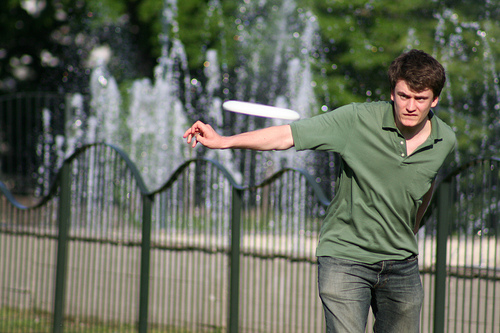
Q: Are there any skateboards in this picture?
A: No, there are no skateboards.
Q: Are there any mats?
A: No, there are no mats.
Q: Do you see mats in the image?
A: No, there are no mats.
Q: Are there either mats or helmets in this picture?
A: No, there are no mats or helmets.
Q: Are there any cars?
A: No, there are no cars.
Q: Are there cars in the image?
A: No, there are no cars.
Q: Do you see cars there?
A: No, there are no cars.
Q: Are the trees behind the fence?
A: Yes, the trees are behind the fence.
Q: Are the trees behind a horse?
A: No, the trees are behind the fence.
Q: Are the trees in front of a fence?
A: No, the trees are behind a fence.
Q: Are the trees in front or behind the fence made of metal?
A: The trees are behind the fence.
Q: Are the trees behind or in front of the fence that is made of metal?
A: The trees are behind the fence.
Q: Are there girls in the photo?
A: No, there are no girls.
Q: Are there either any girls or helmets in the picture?
A: No, there are no girls or helmets.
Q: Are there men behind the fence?
A: Yes, there is a man behind the fence.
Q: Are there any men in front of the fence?
A: No, the man is behind the fence.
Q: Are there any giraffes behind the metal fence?
A: No, there is a man behind the fence.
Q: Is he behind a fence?
A: Yes, the man is behind a fence.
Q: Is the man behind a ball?
A: No, the man is behind a fence.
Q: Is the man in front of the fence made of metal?
A: No, the man is behind the fence.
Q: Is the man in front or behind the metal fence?
A: The man is behind the fence.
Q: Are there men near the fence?
A: Yes, there is a man near the fence.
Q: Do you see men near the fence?
A: Yes, there is a man near the fence.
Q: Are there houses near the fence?
A: No, there is a man near the fence.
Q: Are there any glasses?
A: No, there are no glasses.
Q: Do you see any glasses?
A: No, there are no glasses.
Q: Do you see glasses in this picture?
A: No, there are no glasses.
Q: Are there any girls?
A: No, there are no girls.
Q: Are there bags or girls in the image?
A: No, there are no girls or bags.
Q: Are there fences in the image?
A: Yes, there is a fence.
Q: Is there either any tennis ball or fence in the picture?
A: Yes, there is a fence.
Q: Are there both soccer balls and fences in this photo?
A: No, there is a fence but no soccer balls.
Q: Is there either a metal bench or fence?
A: Yes, there is a metal fence.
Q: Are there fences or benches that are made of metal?
A: Yes, the fence is made of metal.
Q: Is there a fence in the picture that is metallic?
A: Yes, there is a fence that is metallic.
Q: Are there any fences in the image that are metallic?
A: Yes, there is a fence that is metallic.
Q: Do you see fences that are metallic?
A: Yes, there is a fence that is metallic.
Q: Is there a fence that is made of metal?
A: Yes, there is a fence that is made of metal.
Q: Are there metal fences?
A: Yes, there is a fence that is made of metal.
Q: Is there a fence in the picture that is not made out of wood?
A: Yes, there is a fence that is made of metal.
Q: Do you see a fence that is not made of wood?
A: Yes, there is a fence that is made of metal.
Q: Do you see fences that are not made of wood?
A: Yes, there is a fence that is made of metal.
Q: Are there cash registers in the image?
A: No, there are no cash registers.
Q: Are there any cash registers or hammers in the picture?
A: No, there are no cash registers or hammers.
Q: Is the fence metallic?
A: Yes, the fence is metallic.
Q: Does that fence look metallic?
A: Yes, the fence is metallic.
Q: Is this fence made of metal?
A: Yes, the fence is made of metal.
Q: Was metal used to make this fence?
A: Yes, the fence is made of metal.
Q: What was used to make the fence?
A: The fence is made of metal.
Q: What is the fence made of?
A: The fence is made of metal.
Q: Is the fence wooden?
A: No, the fence is metallic.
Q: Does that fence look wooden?
A: No, the fence is metallic.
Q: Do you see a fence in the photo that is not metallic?
A: No, there is a fence but it is metallic.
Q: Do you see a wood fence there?
A: No, there is a fence but it is made of metal.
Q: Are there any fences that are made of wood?
A: No, there is a fence but it is made of metal.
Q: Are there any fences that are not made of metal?
A: No, there is a fence but it is made of metal.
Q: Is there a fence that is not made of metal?
A: No, there is a fence but it is made of metal.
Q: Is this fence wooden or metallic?
A: The fence is metallic.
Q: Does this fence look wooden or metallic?
A: The fence is metallic.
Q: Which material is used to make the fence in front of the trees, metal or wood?
A: The fence is made of metal.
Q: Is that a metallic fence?
A: Yes, that is a metallic fence.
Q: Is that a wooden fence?
A: No, that is a metallic fence.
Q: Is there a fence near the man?
A: Yes, there is a fence near the man.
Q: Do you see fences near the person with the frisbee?
A: Yes, there is a fence near the man.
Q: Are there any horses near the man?
A: No, there is a fence near the man.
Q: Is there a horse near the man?
A: No, there is a fence near the man.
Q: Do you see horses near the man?
A: No, there is a fence near the man.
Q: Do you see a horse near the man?
A: No, there is a fence near the man.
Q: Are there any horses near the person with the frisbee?
A: No, there is a fence near the man.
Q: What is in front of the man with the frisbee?
A: The fence is in front of the man.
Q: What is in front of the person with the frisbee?
A: The fence is in front of the man.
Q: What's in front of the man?
A: The fence is in front of the man.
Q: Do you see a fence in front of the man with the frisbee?
A: Yes, there is a fence in front of the man.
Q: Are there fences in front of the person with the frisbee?
A: Yes, there is a fence in front of the man.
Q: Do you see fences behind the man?
A: No, the fence is in front of the man.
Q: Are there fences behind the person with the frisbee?
A: No, the fence is in front of the man.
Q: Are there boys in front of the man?
A: No, there is a fence in front of the man.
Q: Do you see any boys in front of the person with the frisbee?
A: No, there is a fence in front of the man.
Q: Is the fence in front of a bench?
A: No, the fence is in front of the man.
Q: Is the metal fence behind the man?
A: No, the fence is in front of the man.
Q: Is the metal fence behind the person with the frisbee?
A: No, the fence is in front of the man.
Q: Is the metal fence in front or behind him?
A: The fence is in front of the man.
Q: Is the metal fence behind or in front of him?
A: The fence is in front of the man.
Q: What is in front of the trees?
A: The fence is in front of the trees.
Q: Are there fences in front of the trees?
A: Yes, there is a fence in front of the trees.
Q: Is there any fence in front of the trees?
A: Yes, there is a fence in front of the trees.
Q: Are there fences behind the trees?
A: No, the fence is in front of the trees.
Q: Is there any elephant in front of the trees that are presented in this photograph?
A: No, there is a fence in front of the trees.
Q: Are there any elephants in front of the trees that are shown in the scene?
A: No, there is a fence in front of the trees.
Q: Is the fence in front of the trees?
A: Yes, the fence is in front of the trees.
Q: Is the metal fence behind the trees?
A: No, the fence is in front of the trees.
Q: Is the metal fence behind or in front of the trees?
A: The fence is in front of the trees.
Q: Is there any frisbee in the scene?
A: Yes, there is a frisbee.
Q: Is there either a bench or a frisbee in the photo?
A: Yes, there is a frisbee.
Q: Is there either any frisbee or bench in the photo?
A: Yes, there is a frisbee.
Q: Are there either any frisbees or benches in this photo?
A: Yes, there is a frisbee.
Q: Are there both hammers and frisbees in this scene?
A: No, there is a frisbee but no hammers.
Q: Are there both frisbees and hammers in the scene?
A: No, there is a frisbee but no hammers.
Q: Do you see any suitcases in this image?
A: No, there are no suitcases.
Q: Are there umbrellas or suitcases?
A: No, there are no suitcases or umbrellas.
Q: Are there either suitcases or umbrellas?
A: No, there are no suitcases or umbrellas.